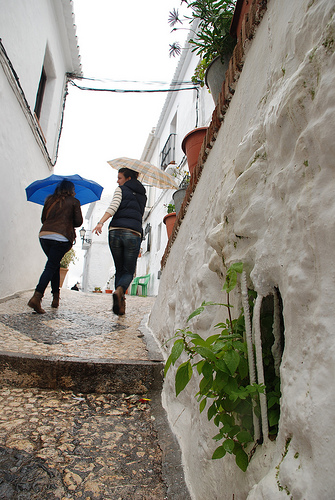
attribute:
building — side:
[78, 182, 135, 293]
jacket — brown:
[41, 193, 82, 240]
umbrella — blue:
[22, 166, 107, 205]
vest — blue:
[109, 178, 147, 233]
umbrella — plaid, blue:
[26, 173, 102, 204]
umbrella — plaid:
[110, 156, 178, 187]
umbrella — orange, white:
[89, 153, 181, 202]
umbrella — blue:
[22, 166, 109, 214]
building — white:
[0, 12, 124, 242]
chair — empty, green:
[125, 271, 154, 300]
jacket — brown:
[32, 189, 93, 226]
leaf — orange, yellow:
[136, 395, 152, 403]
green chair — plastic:
[126, 268, 155, 298]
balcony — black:
[158, 130, 174, 167]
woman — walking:
[27, 177, 84, 312]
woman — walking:
[90, 166, 147, 314]